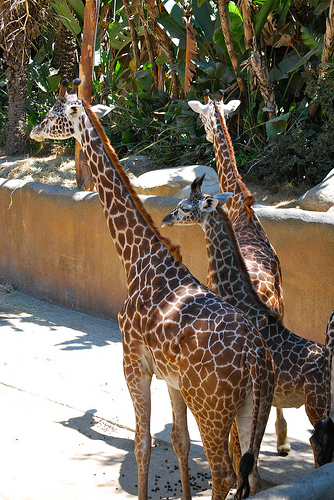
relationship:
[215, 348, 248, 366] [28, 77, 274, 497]
spot on giraffe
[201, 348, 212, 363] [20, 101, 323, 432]
spot on giraffe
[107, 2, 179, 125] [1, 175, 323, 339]
trees growing behind wall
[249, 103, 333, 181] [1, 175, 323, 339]
bush growing behind wall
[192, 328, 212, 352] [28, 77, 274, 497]
spot on giraffe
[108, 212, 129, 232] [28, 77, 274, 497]
spot on giraffe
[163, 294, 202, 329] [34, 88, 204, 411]
spot on giraffe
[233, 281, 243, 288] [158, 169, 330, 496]
spot on giraffe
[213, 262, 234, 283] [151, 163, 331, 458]
spot on giraffe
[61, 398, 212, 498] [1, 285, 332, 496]
shadow on ground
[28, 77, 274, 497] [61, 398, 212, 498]
giraffe has shadow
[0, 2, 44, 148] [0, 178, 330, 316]
tree behind wall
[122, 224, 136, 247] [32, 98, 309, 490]
spot on giraffe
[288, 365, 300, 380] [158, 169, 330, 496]
spot on giraffe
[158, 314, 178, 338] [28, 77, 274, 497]
spot on giraffe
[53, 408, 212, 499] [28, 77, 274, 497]
shadow of giraffe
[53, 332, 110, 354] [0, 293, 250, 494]
shadow on ground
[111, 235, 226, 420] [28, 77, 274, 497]
pattern on giraffe